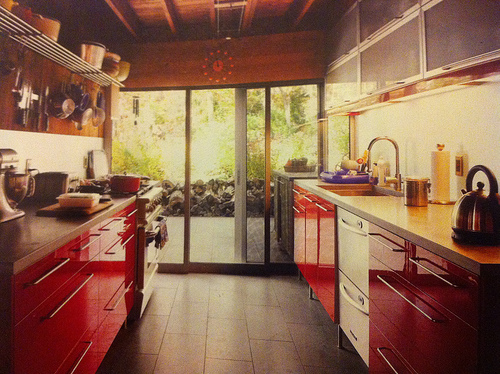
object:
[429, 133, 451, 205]
paper towels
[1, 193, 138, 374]
drawers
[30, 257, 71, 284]
handles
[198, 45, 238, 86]
clock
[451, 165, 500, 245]
kettle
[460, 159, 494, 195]
handle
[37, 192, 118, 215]
cutting board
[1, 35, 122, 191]
wall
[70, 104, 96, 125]
pots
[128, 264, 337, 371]
kitchen floor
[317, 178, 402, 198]
kitchen sink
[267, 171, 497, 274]
countertop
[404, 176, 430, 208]
canister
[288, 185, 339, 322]
cabinet doors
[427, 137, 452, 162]
holder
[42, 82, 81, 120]
pot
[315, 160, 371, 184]
holder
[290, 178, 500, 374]
counter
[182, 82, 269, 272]
door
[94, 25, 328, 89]
wall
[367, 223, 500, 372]
cabinets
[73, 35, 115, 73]
pot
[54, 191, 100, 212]
container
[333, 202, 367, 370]
dishwasher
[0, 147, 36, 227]
mixer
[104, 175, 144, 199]
pot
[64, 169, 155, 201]
stove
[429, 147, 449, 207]
towels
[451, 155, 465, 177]
outlet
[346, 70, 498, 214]
wall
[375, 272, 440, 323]
handle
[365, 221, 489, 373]
drawer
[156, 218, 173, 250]
towel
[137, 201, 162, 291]
door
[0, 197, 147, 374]
cabinets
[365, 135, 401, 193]
faucet